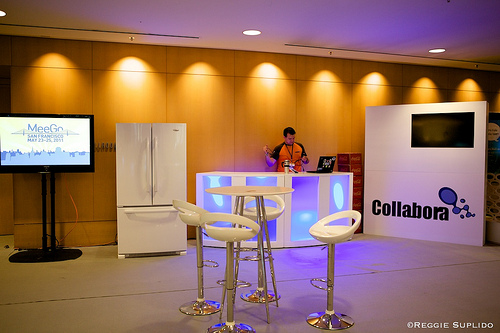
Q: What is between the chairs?
A: Table.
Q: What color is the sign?
A: White.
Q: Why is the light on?
A: To see.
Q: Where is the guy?
A: Behind the desk.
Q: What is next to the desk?
A: Fridge.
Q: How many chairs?
A: 4.